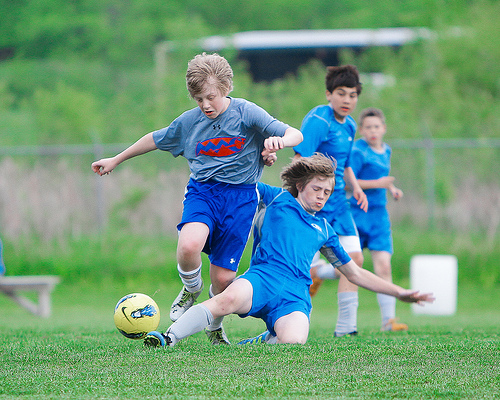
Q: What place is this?
A: It is a field.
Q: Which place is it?
A: It is a field.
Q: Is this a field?
A: Yes, it is a field.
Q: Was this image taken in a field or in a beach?
A: It was taken at a field.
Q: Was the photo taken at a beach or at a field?
A: It was taken at a field.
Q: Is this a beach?
A: No, it is a field.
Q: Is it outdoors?
A: Yes, it is outdoors.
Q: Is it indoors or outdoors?
A: It is outdoors.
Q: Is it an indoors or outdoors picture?
A: It is outdoors.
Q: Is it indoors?
A: No, it is outdoors.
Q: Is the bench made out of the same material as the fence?
A: No, the bench is made of wood and the fence is made of metal.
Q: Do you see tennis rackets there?
A: No, there are no tennis rackets.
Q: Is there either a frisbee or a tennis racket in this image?
A: No, there are no rackets or frisbees.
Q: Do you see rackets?
A: No, there are no rackets.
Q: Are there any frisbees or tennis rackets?
A: No, there are no tennis rackets or frisbees.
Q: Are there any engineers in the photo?
A: No, there are no engineers.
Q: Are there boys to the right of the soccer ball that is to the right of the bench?
A: Yes, there is a boy to the right of the soccer ball.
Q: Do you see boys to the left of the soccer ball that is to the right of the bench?
A: No, the boy is to the right of the soccer ball.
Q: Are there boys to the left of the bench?
A: No, the boy is to the right of the bench.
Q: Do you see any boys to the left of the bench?
A: No, the boy is to the right of the bench.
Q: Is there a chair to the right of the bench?
A: No, there is a boy to the right of the bench.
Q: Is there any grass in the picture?
A: Yes, there is grass.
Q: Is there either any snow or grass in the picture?
A: Yes, there is grass.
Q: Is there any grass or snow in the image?
A: Yes, there is grass.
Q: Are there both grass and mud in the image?
A: No, there is grass but no mud.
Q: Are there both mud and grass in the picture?
A: No, there is grass but no mud.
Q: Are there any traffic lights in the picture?
A: No, there are no traffic lights.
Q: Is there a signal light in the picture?
A: No, there are no traffic lights.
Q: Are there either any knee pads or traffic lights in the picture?
A: No, there are no traffic lights or knee pads.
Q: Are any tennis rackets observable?
A: No, there are no tennis rackets.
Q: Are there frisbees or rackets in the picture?
A: No, there are no rackets or frisbees.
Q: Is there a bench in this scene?
A: Yes, there is a bench.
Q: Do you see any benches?
A: Yes, there is a bench.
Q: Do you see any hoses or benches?
A: Yes, there is a bench.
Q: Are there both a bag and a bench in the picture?
A: No, there is a bench but no bags.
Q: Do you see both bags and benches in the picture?
A: No, there is a bench but no bags.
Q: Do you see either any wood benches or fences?
A: Yes, there is a wood bench.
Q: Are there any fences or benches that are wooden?
A: Yes, the bench is wooden.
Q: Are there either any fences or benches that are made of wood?
A: Yes, the bench is made of wood.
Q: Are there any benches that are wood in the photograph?
A: Yes, there is a wood bench.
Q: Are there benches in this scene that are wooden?
A: Yes, there is a bench that is wooden.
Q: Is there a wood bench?
A: Yes, there is a bench that is made of wood.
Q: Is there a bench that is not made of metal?
A: Yes, there is a bench that is made of wood.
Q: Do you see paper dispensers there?
A: No, there are no paper dispensers.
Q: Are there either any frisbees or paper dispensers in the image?
A: No, there are no paper dispensers or frisbees.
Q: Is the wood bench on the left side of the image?
A: Yes, the bench is on the left of the image.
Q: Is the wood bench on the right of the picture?
A: No, the bench is on the left of the image.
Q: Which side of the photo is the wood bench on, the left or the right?
A: The bench is on the left of the image.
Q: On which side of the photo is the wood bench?
A: The bench is on the left of the image.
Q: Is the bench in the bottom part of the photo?
A: Yes, the bench is in the bottom of the image.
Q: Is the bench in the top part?
A: No, the bench is in the bottom of the image.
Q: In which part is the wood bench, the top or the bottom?
A: The bench is in the bottom of the image.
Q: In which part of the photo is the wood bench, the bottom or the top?
A: The bench is in the bottom of the image.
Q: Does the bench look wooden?
A: Yes, the bench is wooden.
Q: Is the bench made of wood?
A: Yes, the bench is made of wood.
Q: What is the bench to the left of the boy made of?
A: The bench is made of wood.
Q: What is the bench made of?
A: The bench is made of wood.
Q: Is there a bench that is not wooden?
A: No, there is a bench but it is wooden.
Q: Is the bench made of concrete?
A: No, the bench is made of wood.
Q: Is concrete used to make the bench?
A: No, the bench is made of wood.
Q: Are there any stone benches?
A: No, there is a bench but it is made of wood.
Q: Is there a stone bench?
A: No, there is a bench but it is made of wood.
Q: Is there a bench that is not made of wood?
A: No, there is a bench but it is made of wood.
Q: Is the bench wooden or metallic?
A: The bench is wooden.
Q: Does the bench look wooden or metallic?
A: The bench is wooden.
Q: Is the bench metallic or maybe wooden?
A: The bench is wooden.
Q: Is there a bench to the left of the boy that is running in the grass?
A: Yes, there is a bench to the left of the boy.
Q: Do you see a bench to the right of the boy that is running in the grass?
A: No, the bench is to the left of the boy.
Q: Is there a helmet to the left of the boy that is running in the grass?
A: No, there is a bench to the left of the boy.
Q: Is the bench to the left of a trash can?
A: No, the bench is to the left of a boy.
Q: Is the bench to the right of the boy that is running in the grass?
A: No, the bench is to the left of the boy.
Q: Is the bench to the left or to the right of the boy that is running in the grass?
A: The bench is to the left of the boy.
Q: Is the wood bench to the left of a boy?
A: Yes, the bench is to the left of a boy.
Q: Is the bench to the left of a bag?
A: No, the bench is to the left of a boy.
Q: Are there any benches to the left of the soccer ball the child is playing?
A: Yes, there is a bench to the left of the soccer ball.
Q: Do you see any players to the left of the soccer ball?
A: No, there is a bench to the left of the soccer ball.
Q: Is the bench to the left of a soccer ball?
A: Yes, the bench is to the left of a soccer ball.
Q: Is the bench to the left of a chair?
A: No, the bench is to the left of a soccer ball.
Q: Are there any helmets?
A: No, there are no helmets.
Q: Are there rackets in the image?
A: No, there are no rackets.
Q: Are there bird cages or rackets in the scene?
A: No, there are no rackets or bird cages.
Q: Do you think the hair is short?
A: Yes, the hair is short.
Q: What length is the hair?
A: The hair is short.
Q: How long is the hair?
A: The hair is short.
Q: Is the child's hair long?
A: No, the hair is short.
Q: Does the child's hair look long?
A: No, the hair is short.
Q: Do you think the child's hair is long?
A: No, the hair is short.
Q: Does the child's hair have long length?
A: No, the hair is short.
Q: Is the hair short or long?
A: The hair is short.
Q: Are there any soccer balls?
A: Yes, there is a soccer ball.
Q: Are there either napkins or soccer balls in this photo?
A: Yes, there is a soccer ball.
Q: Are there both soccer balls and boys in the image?
A: Yes, there are both a soccer ball and a boy.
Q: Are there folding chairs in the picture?
A: No, there are no folding chairs.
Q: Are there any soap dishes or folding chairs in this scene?
A: No, there are no folding chairs or soap dishes.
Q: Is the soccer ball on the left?
A: Yes, the soccer ball is on the left of the image.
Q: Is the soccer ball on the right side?
A: No, the soccer ball is on the left of the image.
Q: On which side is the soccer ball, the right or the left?
A: The soccer ball is on the left of the image.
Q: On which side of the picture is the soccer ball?
A: The soccer ball is on the left of the image.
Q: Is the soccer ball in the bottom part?
A: Yes, the soccer ball is in the bottom of the image.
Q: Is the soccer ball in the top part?
A: No, the soccer ball is in the bottom of the image.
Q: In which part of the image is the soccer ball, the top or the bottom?
A: The soccer ball is in the bottom of the image.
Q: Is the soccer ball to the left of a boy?
A: Yes, the soccer ball is to the left of a boy.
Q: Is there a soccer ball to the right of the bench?
A: Yes, there is a soccer ball to the right of the bench.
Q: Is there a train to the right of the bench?
A: No, there is a soccer ball to the right of the bench.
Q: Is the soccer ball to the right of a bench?
A: Yes, the soccer ball is to the right of a bench.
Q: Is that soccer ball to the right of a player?
A: No, the soccer ball is to the right of a bench.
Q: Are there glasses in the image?
A: No, there are no glasses.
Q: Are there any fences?
A: Yes, there is a fence.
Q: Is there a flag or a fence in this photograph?
A: Yes, there is a fence.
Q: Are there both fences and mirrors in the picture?
A: No, there is a fence but no mirrors.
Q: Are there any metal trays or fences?
A: Yes, there is a metal fence.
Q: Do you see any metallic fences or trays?
A: Yes, there is a metal fence.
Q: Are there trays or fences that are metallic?
A: Yes, the fence is metallic.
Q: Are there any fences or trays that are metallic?
A: Yes, the fence is metallic.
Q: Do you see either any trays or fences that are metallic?
A: Yes, the fence is metallic.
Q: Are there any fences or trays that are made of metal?
A: Yes, the fence is made of metal.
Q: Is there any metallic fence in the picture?
A: Yes, there is a metal fence.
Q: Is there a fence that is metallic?
A: Yes, there is a fence that is metallic.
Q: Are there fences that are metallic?
A: Yes, there is a fence that is metallic.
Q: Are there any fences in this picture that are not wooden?
A: Yes, there is a metallic fence.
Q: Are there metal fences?
A: Yes, there is a fence that is made of metal.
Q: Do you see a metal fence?
A: Yes, there is a fence that is made of metal.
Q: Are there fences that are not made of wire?
A: Yes, there is a fence that is made of metal.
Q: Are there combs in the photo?
A: No, there are no combs.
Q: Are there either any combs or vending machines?
A: No, there are no combs or vending machines.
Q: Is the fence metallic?
A: Yes, the fence is metallic.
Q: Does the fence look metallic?
A: Yes, the fence is metallic.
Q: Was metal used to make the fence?
A: Yes, the fence is made of metal.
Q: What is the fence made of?
A: The fence is made of metal.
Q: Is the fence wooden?
A: No, the fence is metallic.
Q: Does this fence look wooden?
A: No, the fence is metallic.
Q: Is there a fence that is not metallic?
A: No, there is a fence but it is metallic.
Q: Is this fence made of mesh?
A: No, the fence is made of metal.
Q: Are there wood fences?
A: No, there is a fence but it is made of metal.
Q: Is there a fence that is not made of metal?
A: No, there is a fence but it is made of metal.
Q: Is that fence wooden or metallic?
A: The fence is metallic.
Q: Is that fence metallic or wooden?
A: The fence is metallic.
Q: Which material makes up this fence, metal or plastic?
A: The fence is made of metal.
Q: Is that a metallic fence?
A: Yes, that is a metallic fence.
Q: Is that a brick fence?
A: No, that is a metallic fence.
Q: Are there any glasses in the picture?
A: No, there are no glasses.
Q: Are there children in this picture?
A: Yes, there is a child.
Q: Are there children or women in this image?
A: Yes, there is a child.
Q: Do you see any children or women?
A: Yes, there is a child.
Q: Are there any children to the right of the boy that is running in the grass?
A: Yes, there is a child to the right of the boy.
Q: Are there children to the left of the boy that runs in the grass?
A: No, the child is to the right of the boy.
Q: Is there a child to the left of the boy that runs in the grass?
A: No, the child is to the right of the boy.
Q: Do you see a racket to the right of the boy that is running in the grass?
A: No, there is a child to the right of the boy.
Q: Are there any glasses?
A: No, there are no glasses.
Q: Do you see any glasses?
A: No, there are no glasses.